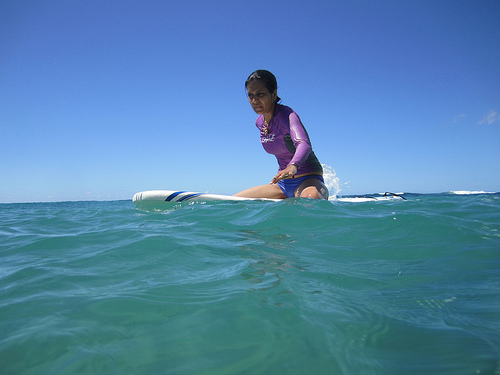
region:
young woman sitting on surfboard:
[218, 61, 344, 215]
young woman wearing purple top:
[256, 115, 318, 170]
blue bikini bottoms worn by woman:
[275, 180, 337, 196]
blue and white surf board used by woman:
[139, 187, 239, 219]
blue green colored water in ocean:
[11, 207, 138, 357]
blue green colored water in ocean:
[143, 213, 358, 343]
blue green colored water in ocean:
[352, 212, 489, 359]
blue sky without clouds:
[11, 11, 160, 182]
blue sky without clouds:
[179, 7, 434, 63]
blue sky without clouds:
[336, 15, 489, 172]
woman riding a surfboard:
[122, 51, 414, 207]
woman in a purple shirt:
[229, 62, 329, 205]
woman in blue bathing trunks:
[222, 66, 333, 209]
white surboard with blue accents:
[125, 184, 416, 211]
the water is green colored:
[1, 194, 498, 374]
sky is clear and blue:
[0, 4, 499, 197]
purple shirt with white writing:
[252, 102, 326, 182]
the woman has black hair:
[234, 61, 334, 205]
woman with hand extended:
[224, 64, 334, 209]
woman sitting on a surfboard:
[115, 63, 410, 205]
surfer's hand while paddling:
[275, 166, 295, 186]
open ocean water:
[132, 245, 267, 297]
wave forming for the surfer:
[450, 185, 490, 195]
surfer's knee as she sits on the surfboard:
[295, 185, 332, 210]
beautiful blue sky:
[75, 55, 200, 135]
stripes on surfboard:
[162, 190, 202, 205]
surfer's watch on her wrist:
[287, 160, 297, 170]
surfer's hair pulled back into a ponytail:
[245, 72, 280, 87]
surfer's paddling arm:
[290, 116, 315, 168]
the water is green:
[62, 212, 373, 330]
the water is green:
[260, 240, 347, 310]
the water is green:
[262, 250, 310, 294]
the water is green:
[252, 237, 280, 268]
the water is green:
[253, 221, 318, 286]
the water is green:
[222, 188, 312, 253]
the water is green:
[246, 217, 291, 249]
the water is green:
[280, 295, 314, 309]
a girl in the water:
[211, 46, 331, 246]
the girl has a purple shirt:
[250, 112, 322, 176]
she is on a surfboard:
[129, 65, 418, 210]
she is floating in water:
[125, 69, 403, 236]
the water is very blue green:
[14, 205, 499, 367]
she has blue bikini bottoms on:
[262, 174, 309, 196]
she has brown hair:
[244, 67, 288, 90]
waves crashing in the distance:
[418, 186, 498, 198]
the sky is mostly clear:
[8, 2, 498, 65]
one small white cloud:
[452, 96, 498, 138]